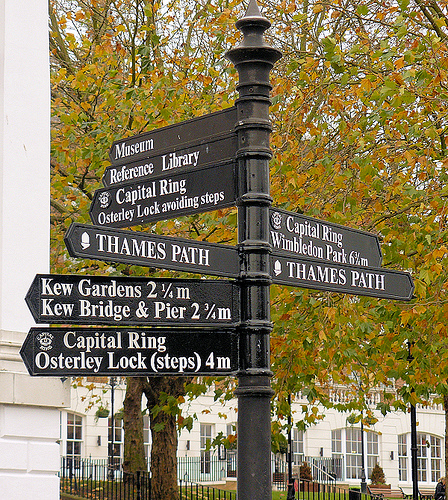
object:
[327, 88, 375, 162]
leaves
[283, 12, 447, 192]
tree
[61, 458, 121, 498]
gate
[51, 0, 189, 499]
tree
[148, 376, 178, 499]
bark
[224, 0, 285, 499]
pole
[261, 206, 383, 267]
sign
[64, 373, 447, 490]
building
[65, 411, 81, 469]
window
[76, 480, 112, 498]
leaves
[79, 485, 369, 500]
ground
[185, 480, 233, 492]
grass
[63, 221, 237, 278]
sign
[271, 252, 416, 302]
thames path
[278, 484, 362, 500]
fence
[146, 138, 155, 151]
lettering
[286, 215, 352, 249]
capitol ring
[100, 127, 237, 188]
sign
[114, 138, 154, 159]
museum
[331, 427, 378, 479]
window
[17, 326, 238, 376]
sign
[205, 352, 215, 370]
number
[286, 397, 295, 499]
post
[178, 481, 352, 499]
area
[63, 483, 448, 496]
street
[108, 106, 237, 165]
arrow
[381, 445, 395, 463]
light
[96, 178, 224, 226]
letter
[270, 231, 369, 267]
letter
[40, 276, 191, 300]
letter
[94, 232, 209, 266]
letter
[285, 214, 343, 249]
letter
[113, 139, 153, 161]
letter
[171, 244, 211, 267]
letter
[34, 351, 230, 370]
letter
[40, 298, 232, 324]
letter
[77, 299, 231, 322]
letter